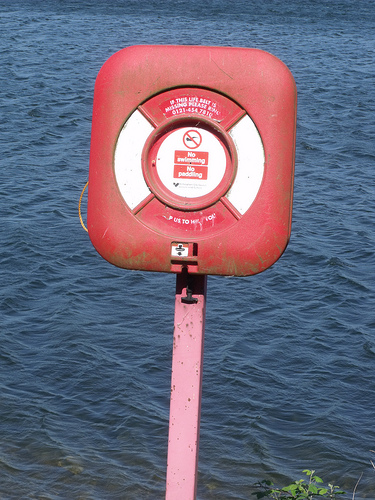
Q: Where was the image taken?
A: It was taken at the lake.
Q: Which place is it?
A: It is a lake.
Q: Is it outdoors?
A: Yes, it is outdoors.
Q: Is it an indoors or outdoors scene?
A: It is outdoors.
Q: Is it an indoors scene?
A: No, it is outdoors.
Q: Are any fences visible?
A: No, there are no fences.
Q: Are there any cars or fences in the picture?
A: No, there are no fences or cars.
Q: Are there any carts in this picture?
A: No, there are no carts.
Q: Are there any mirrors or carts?
A: No, there are no carts or mirrors.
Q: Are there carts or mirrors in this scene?
A: No, there are no carts or mirrors.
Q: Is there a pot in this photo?
A: No, there are no pots.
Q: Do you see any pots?
A: No, there are no pots.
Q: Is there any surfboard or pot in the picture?
A: No, there are no pots or surfboards.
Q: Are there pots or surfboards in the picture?
A: No, there are no pots or surfboards.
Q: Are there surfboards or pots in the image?
A: No, there are no pots or surfboards.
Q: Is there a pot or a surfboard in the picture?
A: No, there are no pots or surfboards.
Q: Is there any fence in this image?
A: No, there are no fences.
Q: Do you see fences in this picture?
A: No, there are no fences.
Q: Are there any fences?
A: No, there are no fences.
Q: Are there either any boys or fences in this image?
A: No, there are no fences or boys.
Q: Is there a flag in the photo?
A: No, there are no flags.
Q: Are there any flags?
A: No, there are no flags.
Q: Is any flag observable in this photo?
A: No, there are no flags.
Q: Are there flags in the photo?
A: No, there are no flags.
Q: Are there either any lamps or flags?
A: No, there are no flags or lamps.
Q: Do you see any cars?
A: No, there are no cars.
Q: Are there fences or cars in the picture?
A: No, there are no cars or fences.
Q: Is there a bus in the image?
A: No, there are no buses.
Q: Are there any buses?
A: No, there are no buses.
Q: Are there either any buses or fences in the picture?
A: No, there are no buses or fences.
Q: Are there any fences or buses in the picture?
A: No, there are no buses or fences.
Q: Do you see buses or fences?
A: No, there are no buses or fences.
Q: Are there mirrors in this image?
A: No, there are no mirrors.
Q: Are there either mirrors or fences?
A: No, there are no mirrors or fences.